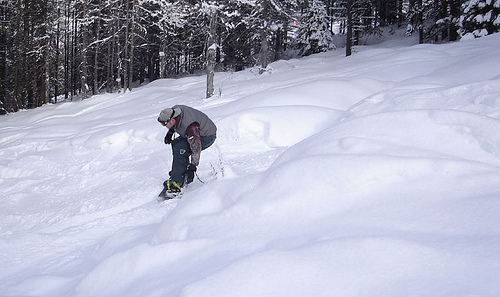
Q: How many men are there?
A: One.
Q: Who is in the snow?
A: The man.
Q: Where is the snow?
A: On the ground.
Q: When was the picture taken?
A: Daytime.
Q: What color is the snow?
A: White.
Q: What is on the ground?
A: Snow.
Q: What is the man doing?
A: Skiing.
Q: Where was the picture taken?
A: Outdoors in the snow.